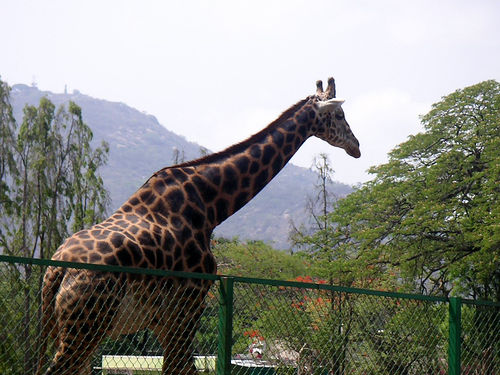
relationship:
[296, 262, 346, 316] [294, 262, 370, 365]
flowers are growing on tree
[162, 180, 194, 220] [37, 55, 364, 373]
spot attached to giraffe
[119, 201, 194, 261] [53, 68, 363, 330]
spots are on top of giraffe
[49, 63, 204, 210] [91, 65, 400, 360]
mountain range behind giraffe